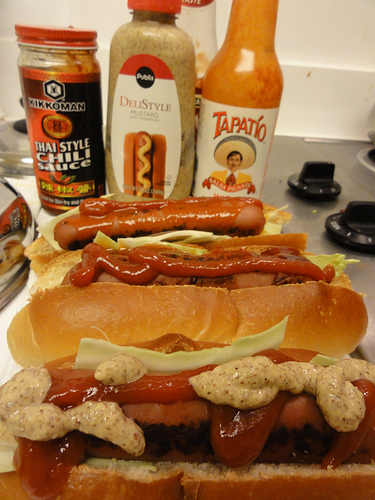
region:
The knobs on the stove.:
[291, 156, 373, 255]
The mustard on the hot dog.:
[5, 354, 363, 439]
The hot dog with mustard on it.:
[53, 408, 367, 457]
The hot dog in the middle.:
[70, 248, 337, 286]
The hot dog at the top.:
[61, 203, 267, 236]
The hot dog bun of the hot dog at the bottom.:
[28, 351, 373, 492]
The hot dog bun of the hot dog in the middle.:
[19, 246, 357, 355]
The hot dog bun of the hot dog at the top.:
[31, 203, 301, 257]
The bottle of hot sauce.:
[188, 10, 272, 196]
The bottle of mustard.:
[104, 2, 194, 195]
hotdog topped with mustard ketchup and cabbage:
[3, 313, 373, 498]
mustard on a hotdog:
[6, 400, 146, 457]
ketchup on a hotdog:
[50, 376, 195, 399]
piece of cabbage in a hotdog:
[71, 313, 292, 365]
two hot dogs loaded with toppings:
[0, 240, 373, 499]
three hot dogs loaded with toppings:
[0, 193, 373, 497]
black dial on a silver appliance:
[284, 155, 346, 199]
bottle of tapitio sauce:
[192, 0, 285, 198]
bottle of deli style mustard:
[104, 0, 195, 197]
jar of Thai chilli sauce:
[11, 21, 109, 216]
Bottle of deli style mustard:
[105, 1, 212, 200]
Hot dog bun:
[6, 285, 367, 359]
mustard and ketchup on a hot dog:
[2, 365, 371, 466]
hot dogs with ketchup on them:
[1, 196, 374, 498]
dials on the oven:
[286, 160, 374, 248]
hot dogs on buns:
[2, 199, 372, 497]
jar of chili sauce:
[15, 24, 106, 219]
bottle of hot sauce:
[194, 5, 282, 205]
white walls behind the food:
[1, 1, 374, 139]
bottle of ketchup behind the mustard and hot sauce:
[174, 2, 219, 137]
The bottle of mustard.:
[112, 2, 192, 210]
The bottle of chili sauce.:
[17, 33, 106, 210]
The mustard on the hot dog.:
[9, 360, 360, 449]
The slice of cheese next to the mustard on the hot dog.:
[79, 326, 299, 367]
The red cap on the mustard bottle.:
[127, 1, 178, 17]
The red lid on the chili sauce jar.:
[13, 21, 99, 51]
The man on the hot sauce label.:
[214, 133, 254, 190]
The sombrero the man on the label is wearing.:
[208, 136, 259, 171]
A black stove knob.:
[285, 157, 342, 202]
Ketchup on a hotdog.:
[64, 240, 334, 285]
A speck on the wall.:
[300, 64, 312, 79]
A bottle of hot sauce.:
[195, 0, 285, 195]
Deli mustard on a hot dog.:
[90, 351, 143, 383]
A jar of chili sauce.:
[8, 19, 98, 206]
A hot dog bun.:
[0, 274, 361, 349]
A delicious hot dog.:
[0, 355, 374, 498]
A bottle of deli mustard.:
[102, 0, 195, 202]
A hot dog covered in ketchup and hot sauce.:
[43, 194, 291, 247]